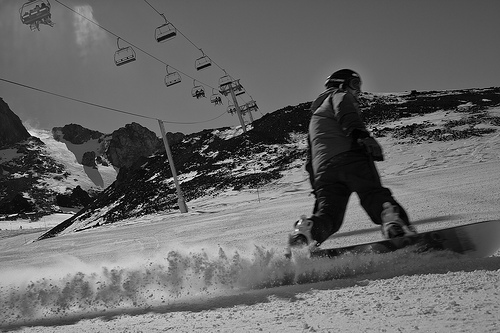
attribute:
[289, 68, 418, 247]
person — snowboarding, boarding, skiing, dressed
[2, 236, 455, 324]
snow — white, raised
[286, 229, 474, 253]
snowboard — tilted, gray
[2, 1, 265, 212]
lift — carrying, grey, supported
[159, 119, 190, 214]
pole — electric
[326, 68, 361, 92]
helmet — black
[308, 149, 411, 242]
pants — black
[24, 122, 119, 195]
snow — covering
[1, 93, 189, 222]
mountain — covered, rocky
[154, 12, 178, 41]
car — empty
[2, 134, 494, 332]
snow — covering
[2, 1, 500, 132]
sky — clear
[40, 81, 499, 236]
hill — covered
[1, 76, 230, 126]
wires — black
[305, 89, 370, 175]
jacket — puffy